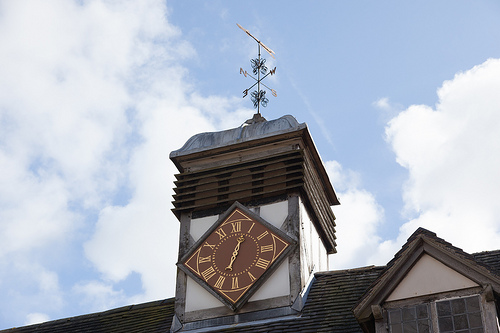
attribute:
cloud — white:
[10, 5, 200, 198]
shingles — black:
[96, 307, 174, 328]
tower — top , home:
[169, 20, 340, 332]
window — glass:
[370, 282, 499, 332]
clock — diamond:
[180, 204, 299, 310]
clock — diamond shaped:
[172, 195, 303, 315]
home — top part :
[346, 213, 488, 331]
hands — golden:
[172, 203, 313, 287]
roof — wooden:
[312, 276, 372, 331]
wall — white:
[387, 243, 479, 305]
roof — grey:
[323, 261, 370, 301]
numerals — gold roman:
[218, 271, 241, 291]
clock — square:
[172, 203, 296, 317]